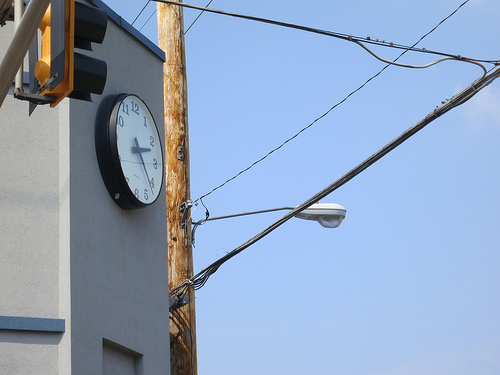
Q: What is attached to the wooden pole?
A: The wires in the air.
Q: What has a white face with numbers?
A: A clock.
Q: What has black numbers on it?
A: A clock.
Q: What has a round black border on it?
A: The clock.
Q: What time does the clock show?
A: 2:22.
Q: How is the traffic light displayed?
A: Hanging.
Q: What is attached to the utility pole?
A: Street light and electric wires.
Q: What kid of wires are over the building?
A: Electrical.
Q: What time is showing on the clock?
A: 2:22.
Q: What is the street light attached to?
A: Utility pole.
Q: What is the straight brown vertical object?
A: Utility pole.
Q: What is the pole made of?
A: Wood.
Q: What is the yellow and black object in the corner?
A: Traffic light.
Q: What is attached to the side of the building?
A: A clock.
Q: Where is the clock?
A: On the wall.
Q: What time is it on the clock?
A: 222.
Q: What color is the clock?
A: White and black.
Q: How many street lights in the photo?
A: One.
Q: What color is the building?
A: Off white and blue.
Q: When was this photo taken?
A: During the day.